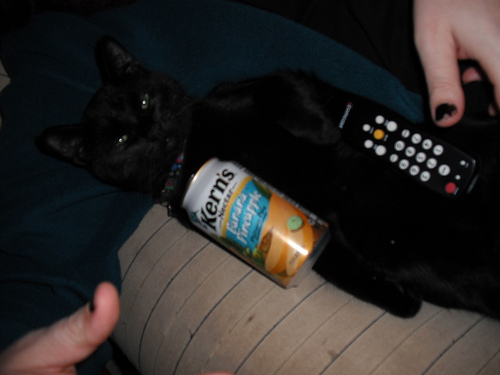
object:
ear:
[45, 119, 79, 161]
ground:
[438, 192, 495, 225]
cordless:
[325, 82, 484, 201]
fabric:
[115, 230, 500, 375]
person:
[0, 0, 499, 375]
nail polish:
[433, 101, 456, 123]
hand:
[408, 0, 499, 127]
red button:
[444, 182, 456, 195]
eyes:
[115, 135, 127, 146]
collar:
[161, 144, 189, 208]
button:
[373, 129, 384, 138]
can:
[182, 154, 331, 287]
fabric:
[0, 0, 426, 303]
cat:
[36, 31, 500, 322]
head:
[38, 32, 190, 183]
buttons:
[397, 123, 437, 177]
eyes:
[141, 92, 151, 109]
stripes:
[115, 208, 345, 375]